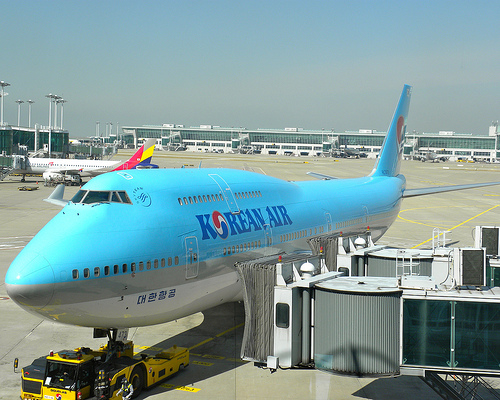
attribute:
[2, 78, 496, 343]
jet — on the plane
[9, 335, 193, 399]
vehicle — yellow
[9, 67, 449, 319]
jetliner — parked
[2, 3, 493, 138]
sky — blue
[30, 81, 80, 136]
lights — around building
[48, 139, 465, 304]
plane — with logo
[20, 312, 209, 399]
vehicle — under plane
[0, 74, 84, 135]
light poles — tall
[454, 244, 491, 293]
ac unit — tall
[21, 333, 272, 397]
cart — yellow, long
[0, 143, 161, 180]
jet — parked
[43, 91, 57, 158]
lamp pole — tall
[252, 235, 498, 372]
walkway — next to plane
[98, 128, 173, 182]
wing — red blue and yellow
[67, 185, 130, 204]
windows — on the plane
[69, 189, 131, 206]
window — on the plane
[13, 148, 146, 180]
white plane — small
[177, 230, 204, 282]
door — blue, white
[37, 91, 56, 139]
pole light — at airport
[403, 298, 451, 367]
glass — panel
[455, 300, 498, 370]
glass — panel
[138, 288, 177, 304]
letters — blue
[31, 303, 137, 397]
truck — yellow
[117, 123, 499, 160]
building — around building, in airport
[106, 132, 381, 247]
plane — blue 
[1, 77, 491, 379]
plane — blue, large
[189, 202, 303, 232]
letters — blue